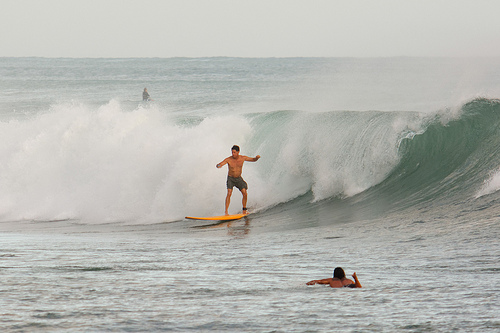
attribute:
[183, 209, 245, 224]
surfboard — bright yellow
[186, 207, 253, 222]
surfboard — yellow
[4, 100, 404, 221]
waves — white, green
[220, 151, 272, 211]
person — barely visible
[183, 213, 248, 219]
surfboard — yellow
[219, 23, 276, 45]
sky — blue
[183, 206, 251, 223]
surf board — yellow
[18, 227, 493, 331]
water — calm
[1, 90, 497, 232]
wave — splashing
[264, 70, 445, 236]
ocean water — spraying up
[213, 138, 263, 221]
man — surfing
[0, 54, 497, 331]
ocean — gray, blue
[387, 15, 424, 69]
clouds — white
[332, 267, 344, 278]
hair — dark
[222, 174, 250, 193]
short — gray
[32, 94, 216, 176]
spray — white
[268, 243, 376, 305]
man — swimming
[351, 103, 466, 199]
wave — large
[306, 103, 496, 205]
waves — rippled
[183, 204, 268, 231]
surfboard — yellow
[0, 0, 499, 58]
sky — pale blue, blue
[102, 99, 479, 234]
water — large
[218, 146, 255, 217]
man — balancing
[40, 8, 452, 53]
clouds — white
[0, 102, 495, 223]
ocean wave — breaking, large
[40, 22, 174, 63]
sky — blue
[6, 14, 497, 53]
sky — blue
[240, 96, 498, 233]
wave — large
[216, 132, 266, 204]
man — dark-haired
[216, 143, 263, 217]
he — surfing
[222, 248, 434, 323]
water — shoulder-length